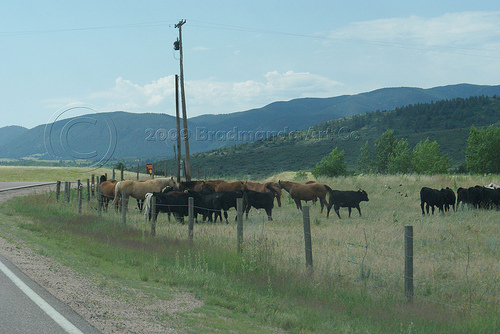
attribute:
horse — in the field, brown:
[98, 174, 327, 197]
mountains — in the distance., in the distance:
[0, 83, 499, 162]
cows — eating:
[420, 183, 499, 214]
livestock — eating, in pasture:
[96, 179, 499, 221]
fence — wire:
[54, 158, 497, 330]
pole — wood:
[402, 224, 414, 305]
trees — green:
[293, 122, 499, 177]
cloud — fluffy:
[43, 69, 355, 120]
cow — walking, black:
[322, 184, 372, 219]